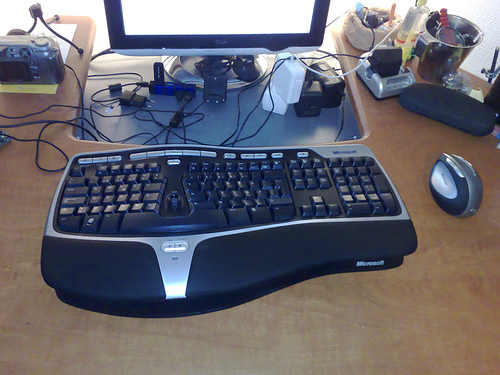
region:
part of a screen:
[228, 2, 249, 22]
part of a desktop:
[345, 279, 401, 346]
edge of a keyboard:
[180, 291, 238, 326]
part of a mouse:
[433, 132, 483, 212]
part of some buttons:
[191, 199, 250, 255]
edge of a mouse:
[414, 167, 446, 210]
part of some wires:
[162, 107, 224, 144]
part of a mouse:
[443, 148, 470, 205]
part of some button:
[146, 182, 191, 213]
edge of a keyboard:
[224, 268, 278, 293]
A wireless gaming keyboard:
[37, 140, 414, 331]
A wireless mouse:
[420, 141, 480, 226]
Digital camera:
[0, 31, 65, 88]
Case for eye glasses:
[396, 77, 486, 142]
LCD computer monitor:
[105, 0, 320, 52]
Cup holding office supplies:
[410, 5, 480, 85]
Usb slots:
[150, 60, 195, 100]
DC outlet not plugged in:
[300, 60, 350, 115]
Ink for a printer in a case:
[395, 0, 420, 55]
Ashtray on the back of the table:
[340, 0, 396, 47]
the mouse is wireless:
[423, 147, 484, 248]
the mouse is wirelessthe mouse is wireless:
[427, 135, 477, 192]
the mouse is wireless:
[442, 164, 487, 211]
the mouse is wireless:
[407, 132, 498, 286]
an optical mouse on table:
[362, 129, 498, 219]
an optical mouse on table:
[391, 141, 498, 306]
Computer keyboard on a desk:
[32, 141, 419, 321]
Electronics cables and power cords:
[55, 60, 370, 145]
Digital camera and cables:
[0, 20, 70, 175]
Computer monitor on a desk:
[100, 0, 325, 105]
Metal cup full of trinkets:
[415, 0, 475, 86]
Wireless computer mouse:
[423, 149, 485, 229]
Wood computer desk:
[23, 312, 490, 374]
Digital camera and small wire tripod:
[0, 0, 85, 93]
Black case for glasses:
[400, 76, 495, 143]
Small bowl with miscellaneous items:
[343, 2, 402, 49]